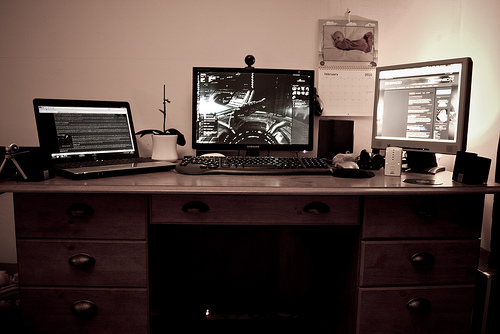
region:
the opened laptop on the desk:
[32, 95, 178, 177]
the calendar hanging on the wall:
[317, 16, 379, 116]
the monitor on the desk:
[192, 67, 317, 156]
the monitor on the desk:
[371, 55, 473, 174]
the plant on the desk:
[135, 84, 185, 161]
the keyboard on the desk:
[175, 155, 330, 174]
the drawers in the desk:
[14, 193, 484, 333]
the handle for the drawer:
[67, 252, 93, 270]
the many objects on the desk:
[0, 53, 492, 183]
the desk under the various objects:
[0, 53, 497, 332]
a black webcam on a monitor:
[242, 51, 255, 72]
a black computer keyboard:
[172, 153, 333, 178]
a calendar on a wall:
[316, 8, 379, 118]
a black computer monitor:
[193, 65, 317, 151]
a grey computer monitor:
[370, 56, 474, 153]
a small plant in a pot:
[135, 81, 184, 144]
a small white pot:
[150, 131, 181, 162]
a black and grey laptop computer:
[31, 98, 176, 181]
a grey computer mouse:
[333, 158, 362, 170]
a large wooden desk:
[1, 159, 499, 332]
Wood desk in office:
[3, 167, 493, 330]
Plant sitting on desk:
[136, 80, 186, 162]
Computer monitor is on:
[370, 55, 466, 150]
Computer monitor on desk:
[191, 65, 311, 147]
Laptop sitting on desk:
[30, 92, 170, 177]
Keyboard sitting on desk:
[175, 150, 331, 170]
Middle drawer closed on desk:
[150, 190, 360, 225]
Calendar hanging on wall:
[311, 13, 377, 118]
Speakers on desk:
[315, 118, 351, 159]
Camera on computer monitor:
[239, 54, 258, 69]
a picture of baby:
[314, 13, 378, 63]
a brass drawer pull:
[66, 202, 88, 219]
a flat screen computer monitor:
[194, 65, 315, 149]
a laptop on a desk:
[26, 95, 163, 177]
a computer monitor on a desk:
[365, 60, 460, 159]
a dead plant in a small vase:
[147, 85, 177, 133]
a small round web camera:
[245, 50, 262, 69]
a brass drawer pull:
[407, 293, 428, 311]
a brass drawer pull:
[66, 295, 123, 330]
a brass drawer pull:
[297, 200, 337, 220]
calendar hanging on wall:
[315, 17, 377, 117]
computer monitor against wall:
[191, 66, 331, 148]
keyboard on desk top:
[181, 156, 329, 172]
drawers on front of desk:
[15, 192, 485, 327]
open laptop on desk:
[32, 98, 172, 179]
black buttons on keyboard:
[185, 157, 323, 168]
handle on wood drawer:
[68, 252, 91, 272]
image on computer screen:
[373, 62, 462, 141]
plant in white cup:
[149, 84, 189, 164]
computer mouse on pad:
[336, 160, 373, 177]